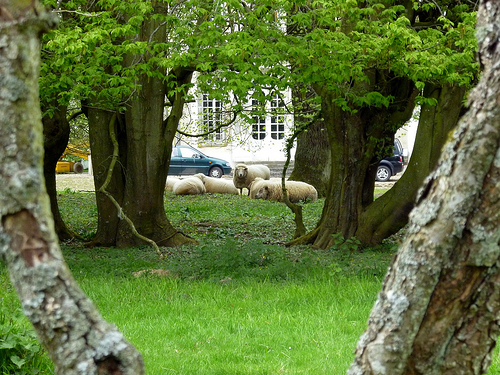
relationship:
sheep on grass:
[249, 174, 322, 206] [136, 243, 346, 373]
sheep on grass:
[230, 159, 275, 201] [136, 243, 346, 373]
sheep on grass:
[194, 172, 251, 201] [136, 243, 346, 373]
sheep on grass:
[174, 173, 207, 196] [136, 243, 346, 373]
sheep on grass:
[159, 170, 199, 196] [136, 243, 346, 373]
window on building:
[249, 89, 287, 141] [242, 111, 274, 163]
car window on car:
[179, 147, 196, 157] [167, 138, 227, 176]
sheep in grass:
[174, 173, 207, 196] [172, 254, 284, 310]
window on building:
[249, 89, 287, 141] [190, 89, 281, 176]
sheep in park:
[253, 176, 319, 204] [1, 2, 497, 371]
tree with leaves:
[5, 196, 106, 373] [282, 92, 316, 127]